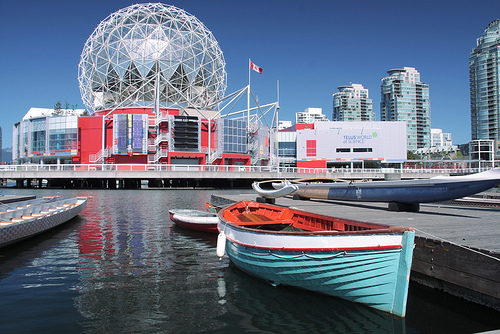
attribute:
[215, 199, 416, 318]
boat — turquoise, red, small, blue, wooden, white, aqua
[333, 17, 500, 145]
buildings — tall, large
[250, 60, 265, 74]
flag — white, red, canadian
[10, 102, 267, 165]
building — red, modern, bright red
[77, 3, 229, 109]
circle — big, glass, large, white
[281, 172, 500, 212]
boat — blue, large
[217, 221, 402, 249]
stripe — white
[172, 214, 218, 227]
bumper — white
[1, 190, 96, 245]
boat — silver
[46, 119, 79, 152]
windows — glass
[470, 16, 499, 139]
building — a high rise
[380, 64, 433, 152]
building — a high rise, blue, large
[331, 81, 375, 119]
building — a high rise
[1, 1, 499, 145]
sky — blue